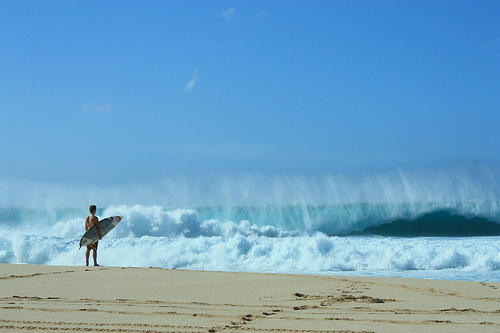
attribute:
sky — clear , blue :
[0, 0, 497, 193]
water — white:
[3, 199, 498, 282]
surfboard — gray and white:
[71, 209, 131, 256]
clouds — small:
[176, 68, 206, 100]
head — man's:
[87, 202, 97, 215]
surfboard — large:
[77, 214, 124, 249]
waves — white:
[22, 192, 497, 283]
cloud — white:
[182, 68, 213, 94]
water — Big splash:
[2, 170, 497, 282]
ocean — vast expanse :
[2, 174, 498, 279]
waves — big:
[5, 188, 496, 276]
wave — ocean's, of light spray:
[138, 146, 410, 268]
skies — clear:
[6, 0, 493, 125]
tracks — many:
[36, 289, 458, 331]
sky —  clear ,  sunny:
[7, 15, 497, 157]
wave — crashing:
[0, 182, 499, 284]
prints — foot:
[277, 274, 328, 323]